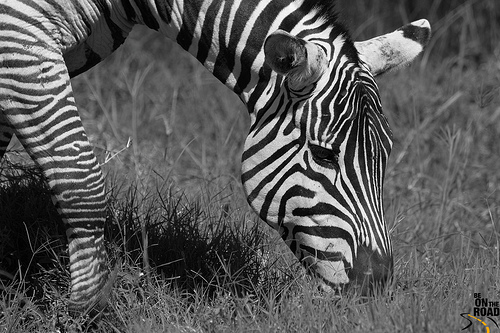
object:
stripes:
[250, 139, 334, 235]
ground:
[0, 10, 500, 333]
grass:
[0, 10, 500, 333]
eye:
[309, 145, 336, 163]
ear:
[264, 29, 326, 90]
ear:
[353, 18, 431, 77]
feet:
[64, 292, 110, 333]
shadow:
[0, 171, 270, 293]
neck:
[193, 0, 279, 88]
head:
[239, 80, 394, 301]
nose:
[351, 246, 395, 297]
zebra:
[0, 0, 428, 333]